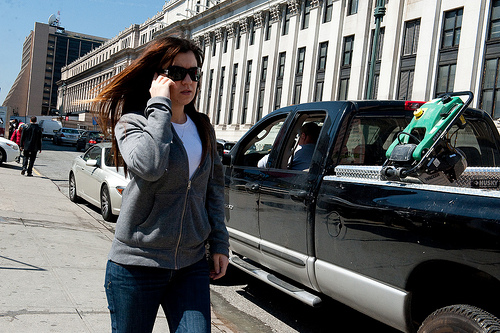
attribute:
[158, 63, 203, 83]
sunglasses — black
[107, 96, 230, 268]
hoody — grey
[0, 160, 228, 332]
floor — grey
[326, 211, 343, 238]
door — round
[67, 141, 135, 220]
car — grey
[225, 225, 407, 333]
trim — grey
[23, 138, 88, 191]
asphalt — black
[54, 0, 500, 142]
building — white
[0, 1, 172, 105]
skies — blue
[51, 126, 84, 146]
car — silver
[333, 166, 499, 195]
box — grey, metal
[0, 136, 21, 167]
car — white